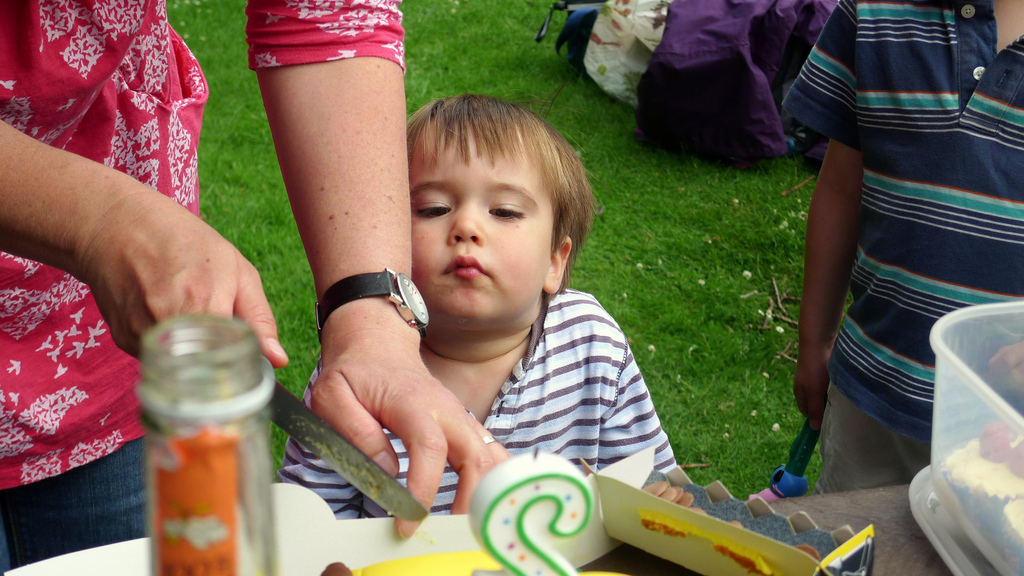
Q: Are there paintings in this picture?
A: No, there are no paintings.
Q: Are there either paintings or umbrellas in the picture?
A: No, there are no paintings or umbrellas.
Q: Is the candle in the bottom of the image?
A: Yes, the candle is in the bottom of the image.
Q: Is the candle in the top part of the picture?
A: No, the candle is in the bottom of the image.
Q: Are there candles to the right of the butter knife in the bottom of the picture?
A: Yes, there is a candle to the right of the butter knife.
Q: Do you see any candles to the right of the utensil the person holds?
A: Yes, there is a candle to the right of the butter knife.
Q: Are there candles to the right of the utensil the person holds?
A: Yes, there is a candle to the right of the butter knife.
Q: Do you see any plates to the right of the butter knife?
A: No, there is a candle to the right of the butter knife.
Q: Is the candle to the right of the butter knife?
A: Yes, the candle is to the right of the butter knife.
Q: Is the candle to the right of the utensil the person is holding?
A: Yes, the candle is to the right of the butter knife.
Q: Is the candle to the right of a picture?
A: No, the candle is to the right of the butter knife.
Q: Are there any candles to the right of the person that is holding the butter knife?
A: Yes, there is a candle to the right of the person.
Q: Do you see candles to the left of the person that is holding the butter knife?
A: No, the candle is to the right of the person.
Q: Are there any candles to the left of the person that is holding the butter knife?
A: No, the candle is to the right of the person.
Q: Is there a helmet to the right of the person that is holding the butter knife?
A: No, there is a candle to the right of the person.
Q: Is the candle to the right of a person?
A: Yes, the candle is to the right of a person.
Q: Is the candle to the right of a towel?
A: No, the candle is to the right of a person.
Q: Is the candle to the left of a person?
A: No, the candle is to the right of a person.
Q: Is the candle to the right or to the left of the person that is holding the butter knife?
A: The candle is to the right of the person.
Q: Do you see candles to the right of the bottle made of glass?
A: Yes, there is a candle to the right of the bottle.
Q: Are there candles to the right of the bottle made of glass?
A: Yes, there is a candle to the right of the bottle.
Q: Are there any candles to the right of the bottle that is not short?
A: Yes, there is a candle to the right of the bottle.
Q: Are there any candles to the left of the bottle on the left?
A: No, the candle is to the right of the bottle.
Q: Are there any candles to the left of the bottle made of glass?
A: No, the candle is to the right of the bottle.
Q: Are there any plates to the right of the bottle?
A: No, there is a candle to the right of the bottle.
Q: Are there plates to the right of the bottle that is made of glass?
A: No, there is a candle to the right of the bottle.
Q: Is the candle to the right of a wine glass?
A: No, the candle is to the right of the bottle.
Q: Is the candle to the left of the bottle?
A: No, the candle is to the right of the bottle.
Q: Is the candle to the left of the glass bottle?
A: No, the candle is to the right of the bottle.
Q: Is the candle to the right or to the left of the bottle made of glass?
A: The candle is to the right of the bottle.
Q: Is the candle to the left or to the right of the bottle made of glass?
A: The candle is to the right of the bottle.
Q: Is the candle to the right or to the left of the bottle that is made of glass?
A: The candle is to the right of the bottle.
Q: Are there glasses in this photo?
A: No, there are no glasses.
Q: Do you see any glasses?
A: No, there are no glasses.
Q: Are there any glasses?
A: No, there are no glasses.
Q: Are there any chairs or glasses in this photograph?
A: No, there are no glasses or chairs.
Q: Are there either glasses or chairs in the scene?
A: No, there are no glasses or chairs.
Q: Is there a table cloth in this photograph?
A: No, there are no tablecloths.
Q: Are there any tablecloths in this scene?
A: No, there are no tablecloths.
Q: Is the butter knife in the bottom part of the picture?
A: Yes, the butter knife is in the bottom of the image.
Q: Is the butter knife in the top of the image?
A: No, the butter knife is in the bottom of the image.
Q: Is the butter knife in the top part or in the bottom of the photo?
A: The butter knife is in the bottom of the image.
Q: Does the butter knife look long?
A: Yes, the butter knife is long.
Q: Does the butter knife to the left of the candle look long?
A: Yes, the butter knife is long.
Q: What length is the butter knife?
A: The butter knife is long.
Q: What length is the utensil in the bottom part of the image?
A: The butter knife is long.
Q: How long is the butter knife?
A: The butter knife is long.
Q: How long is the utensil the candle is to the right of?
A: The butter knife is long.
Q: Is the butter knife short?
A: No, the butter knife is long.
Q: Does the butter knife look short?
A: No, the butter knife is long.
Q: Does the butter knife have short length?
A: No, the butter knife is long.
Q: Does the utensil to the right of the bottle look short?
A: No, the butter knife is long.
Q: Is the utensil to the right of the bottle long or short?
A: The butter knife is long.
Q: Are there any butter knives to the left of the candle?
A: Yes, there is a butter knife to the left of the candle.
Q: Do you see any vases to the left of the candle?
A: No, there is a butter knife to the left of the candle.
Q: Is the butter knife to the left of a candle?
A: Yes, the butter knife is to the left of a candle.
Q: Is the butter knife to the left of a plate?
A: No, the butter knife is to the left of a candle.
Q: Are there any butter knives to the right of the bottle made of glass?
A: Yes, there is a butter knife to the right of the bottle.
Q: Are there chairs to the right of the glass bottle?
A: No, there is a butter knife to the right of the bottle.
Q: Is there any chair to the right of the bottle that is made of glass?
A: No, there is a butter knife to the right of the bottle.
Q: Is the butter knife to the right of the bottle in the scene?
A: Yes, the butter knife is to the right of the bottle.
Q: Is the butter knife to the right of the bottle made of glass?
A: Yes, the butter knife is to the right of the bottle.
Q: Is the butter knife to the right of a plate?
A: No, the butter knife is to the right of the bottle.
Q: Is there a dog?
A: No, there are no dogs.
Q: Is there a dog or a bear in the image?
A: No, there are no dogs or bears.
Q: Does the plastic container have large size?
A: Yes, the container is large.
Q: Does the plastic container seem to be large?
A: Yes, the container is large.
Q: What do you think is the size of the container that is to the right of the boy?
A: The container is large.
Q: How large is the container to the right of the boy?
A: The container is large.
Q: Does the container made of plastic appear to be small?
A: No, the container is large.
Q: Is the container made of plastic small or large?
A: The container is large.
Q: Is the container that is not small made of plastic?
A: Yes, the container is made of plastic.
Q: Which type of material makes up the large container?
A: The container is made of plastic.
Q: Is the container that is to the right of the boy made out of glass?
A: No, the container is made of plastic.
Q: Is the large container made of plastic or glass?
A: The container is made of plastic.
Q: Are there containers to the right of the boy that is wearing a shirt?
A: Yes, there is a container to the right of the boy.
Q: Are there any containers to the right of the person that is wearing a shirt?
A: Yes, there is a container to the right of the boy.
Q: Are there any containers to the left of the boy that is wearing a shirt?
A: No, the container is to the right of the boy.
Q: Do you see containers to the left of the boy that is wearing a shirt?
A: No, the container is to the right of the boy.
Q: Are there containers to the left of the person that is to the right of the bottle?
A: No, the container is to the right of the boy.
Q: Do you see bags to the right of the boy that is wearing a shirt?
A: No, there is a container to the right of the boy.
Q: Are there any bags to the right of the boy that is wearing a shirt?
A: No, there is a container to the right of the boy.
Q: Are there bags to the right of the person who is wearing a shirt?
A: No, there is a container to the right of the boy.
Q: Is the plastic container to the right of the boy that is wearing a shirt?
A: Yes, the container is to the right of the boy.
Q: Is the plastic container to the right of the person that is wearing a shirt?
A: Yes, the container is to the right of the boy.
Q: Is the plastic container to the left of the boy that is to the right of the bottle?
A: No, the container is to the right of the boy.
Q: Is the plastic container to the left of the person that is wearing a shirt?
A: No, the container is to the right of the boy.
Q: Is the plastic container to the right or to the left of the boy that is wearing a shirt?
A: The container is to the right of the boy.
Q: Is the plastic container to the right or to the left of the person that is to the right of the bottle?
A: The container is to the right of the boy.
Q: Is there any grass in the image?
A: Yes, there is grass.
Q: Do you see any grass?
A: Yes, there is grass.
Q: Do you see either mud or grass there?
A: Yes, there is grass.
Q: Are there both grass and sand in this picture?
A: No, there is grass but no sand.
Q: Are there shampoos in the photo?
A: No, there are no shampoos.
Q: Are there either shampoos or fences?
A: No, there are no shampoos or fences.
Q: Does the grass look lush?
A: Yes, the grass is lush.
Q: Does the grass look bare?
A: No, the grass is lush.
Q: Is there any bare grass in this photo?
A: No, there is grass but it is lush.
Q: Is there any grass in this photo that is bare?
A: No, there is grass but it is lush.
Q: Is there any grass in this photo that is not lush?
A: No, there is grass but it is lush.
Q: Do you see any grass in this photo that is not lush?
A: No, there is grass but it is lush.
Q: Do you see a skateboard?
A: No, there are no skateboards.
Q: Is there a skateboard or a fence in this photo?
A: No, there are no skateboards or fences.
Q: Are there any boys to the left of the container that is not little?
A: Yes, there is a boy to the left of the container.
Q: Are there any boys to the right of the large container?
A: No, the boy is to the left of the container.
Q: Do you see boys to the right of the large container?
A: No, the boy is to the left of the container.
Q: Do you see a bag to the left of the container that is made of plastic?
A: No, there is a boy to the left of the container.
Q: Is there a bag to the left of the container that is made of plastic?
A: No, there is a boy to the left of the container.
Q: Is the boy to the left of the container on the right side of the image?
A: Yes, the boy is to the left of the container.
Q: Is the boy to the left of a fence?
A: No, the boy is to the left of the container.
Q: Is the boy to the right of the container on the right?
A: No, the boy is to the left of the container.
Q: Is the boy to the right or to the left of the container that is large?
A: The boy is to the left of the container.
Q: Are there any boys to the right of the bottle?
A: Yes, there is a boy to the right of the bottle.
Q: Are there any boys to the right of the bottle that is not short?
A: Yes, there is a boy to the right of the bottle.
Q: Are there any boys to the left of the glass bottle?
A: No, the boy is to the right of the bottle.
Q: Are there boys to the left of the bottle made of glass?
A: No, the boy is to the right of the bottle.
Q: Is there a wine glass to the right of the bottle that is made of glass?
A: No, there is a boy to the right of the bottle.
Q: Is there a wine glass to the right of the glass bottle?
A: No, there is a boy to the right of the bottle.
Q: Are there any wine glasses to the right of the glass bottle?
A: No, there is a boy to the right of the bottle.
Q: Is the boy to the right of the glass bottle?
A: Yes, the boy is to the right of the bottle.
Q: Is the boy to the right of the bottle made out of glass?
A: Yes, the boy is to the right of the bottle.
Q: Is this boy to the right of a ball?
A: No, the boy is to the right of the bottle.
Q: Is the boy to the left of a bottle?
A: No, the boy is to the right of a bottle.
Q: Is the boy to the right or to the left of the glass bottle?
A: The boy is to the right of the bottle.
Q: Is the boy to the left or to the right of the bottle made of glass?
A: The boy is to the right of the bottle.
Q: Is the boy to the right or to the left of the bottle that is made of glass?
A: The boy is to the right of the bottle.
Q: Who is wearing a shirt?
A: The boy is wearing a shirt.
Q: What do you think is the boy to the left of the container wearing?
A: The boy is wearing a shirt.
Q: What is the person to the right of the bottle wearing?
A: The boy is wearing a shirt.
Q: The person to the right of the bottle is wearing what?
A: The boy is wearing a shirt.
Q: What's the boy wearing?
A: The boy is wearing a shirt.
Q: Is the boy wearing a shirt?
A: Yes, the boy is wearing a shirt.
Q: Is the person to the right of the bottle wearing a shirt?
A: Yes, the boy is wearing a shirt.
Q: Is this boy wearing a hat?
A: No, the boy is wearing a shirt.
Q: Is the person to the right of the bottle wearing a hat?
A: No, the boy is wearing a shirt.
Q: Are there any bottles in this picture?
A: Yes, there is a bottle.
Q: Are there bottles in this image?
A: Yes, there is a bottle.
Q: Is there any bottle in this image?
A: Yes, there is a bottle.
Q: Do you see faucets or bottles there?
A: Yes, there is a bottle.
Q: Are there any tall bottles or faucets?
A: Yes, there is a tall bottle.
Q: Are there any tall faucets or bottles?
A: Yes, there is a tall bottle.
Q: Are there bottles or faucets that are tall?
A: Yes, the bottle is tall.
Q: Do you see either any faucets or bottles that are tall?
A: Yes, the bottle is tall.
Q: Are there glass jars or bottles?
A: Yes, there is a glass bottle.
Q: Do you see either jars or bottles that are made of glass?
A: Yes, the bottle is made of glass.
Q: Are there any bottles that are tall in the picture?
A: Yes, there is a tall bottle.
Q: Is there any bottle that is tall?
A: Yes, there is a bottle that is tall.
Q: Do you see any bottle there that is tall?
A: Yes, there is a bottle that is tall.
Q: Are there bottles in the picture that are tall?
A: Yes, there is a bottle that is tall.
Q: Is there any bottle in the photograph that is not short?
A: Yes, there is a tall bottle.